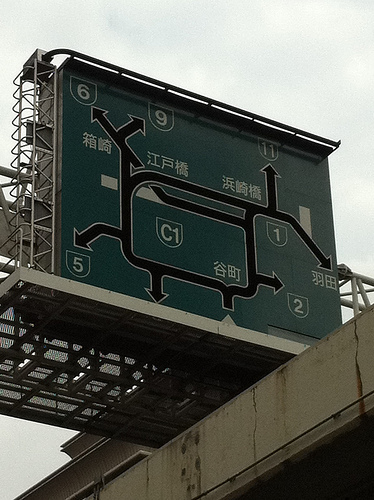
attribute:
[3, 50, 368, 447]
structure — black, large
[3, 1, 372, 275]
clouds — white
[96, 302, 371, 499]
wall — broken, dirty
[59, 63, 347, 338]
traffic sign — green, large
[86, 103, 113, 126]
arrows — black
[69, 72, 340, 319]
characters — foreign, black, white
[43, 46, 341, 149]
bar — metal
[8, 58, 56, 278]
rafters — metal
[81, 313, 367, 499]
bridge — concrete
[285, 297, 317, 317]
number — white, 2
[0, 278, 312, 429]
grate — metal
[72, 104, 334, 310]
arrow map — black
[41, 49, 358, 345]
sign — convoluted, large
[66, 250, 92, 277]
number — 5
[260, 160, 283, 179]
arrow — up